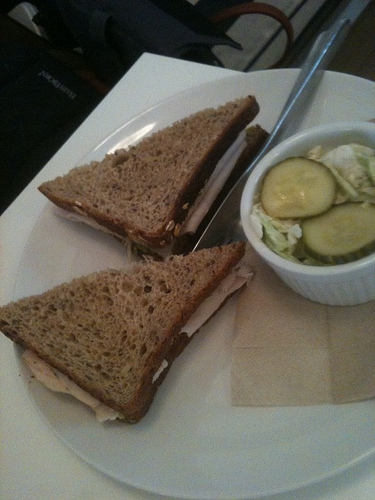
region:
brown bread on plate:
[107, 96, 256, 239]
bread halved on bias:
[30, 82, 242, 409]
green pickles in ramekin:
[284, 155, 363, 269]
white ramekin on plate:
[228, 128, 371, 301]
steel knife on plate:
[178, 44, 336, 262]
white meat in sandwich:
[10, 275, 253, 416]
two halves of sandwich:
[30, 136, 261, 433]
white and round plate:
[17, 134, 363, 483]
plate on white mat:
[44, 112, 364, 482]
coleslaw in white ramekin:
[256, 139, 363, 238]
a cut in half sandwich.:
[36, 91, 267, 257]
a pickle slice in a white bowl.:
[257, 155, 338, 224]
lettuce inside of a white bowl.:
[243, 198, 303, 261]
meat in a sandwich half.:
[174, 125, 252, 243]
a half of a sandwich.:
[0, 239, 255, 424]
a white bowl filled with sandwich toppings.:
[237, 115, 373, 306]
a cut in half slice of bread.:
[0, 237, 248, 405]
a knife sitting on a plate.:
[186, 0, 372, 258]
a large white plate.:
[11, 68, 374, 498]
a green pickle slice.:
[298, 199, 374, 267]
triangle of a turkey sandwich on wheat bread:
[0, 243, 256, 427]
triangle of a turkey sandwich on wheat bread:
[30, 85, 273, 266]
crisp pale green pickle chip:
[259, 145, 344, 221]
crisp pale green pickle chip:
[296, 194, 374, 269]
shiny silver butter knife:
[180, 11, 358, 257]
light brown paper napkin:
[219, 226, 371, 419]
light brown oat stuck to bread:
[162, 217, 176, 232]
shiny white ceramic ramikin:
[237, 113, 373, 312]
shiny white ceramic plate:
[1, 65, 372, 498]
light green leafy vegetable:
[244, 194, 316, 270]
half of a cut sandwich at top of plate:
[35, 94, 270, 261]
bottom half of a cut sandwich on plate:
[1, 239, 255, 425]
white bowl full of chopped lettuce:
[237, 118, 373, 306]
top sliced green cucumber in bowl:
[259, 154, 339, 220]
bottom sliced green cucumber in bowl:
[300, 200, 374, 264]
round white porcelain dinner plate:
[1, 68, 374, 499]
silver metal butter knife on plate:
[170, 1, 373, 254]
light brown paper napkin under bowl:
[230, 238, 374, 406]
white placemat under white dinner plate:
[1, 51, 374, 499]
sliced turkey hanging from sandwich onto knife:
[180, 132, 245, 233]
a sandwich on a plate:
[54, 86, 281, 417]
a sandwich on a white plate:
[48, 88, 322, 427]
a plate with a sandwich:
[13, 214, 306, 487]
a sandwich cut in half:
[41, 232, 281, 495]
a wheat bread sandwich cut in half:
[17, 231, 263, 428]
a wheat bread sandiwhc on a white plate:
[31, 174, 189, 385]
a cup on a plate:
[219, 166, 372, 371]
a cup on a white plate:
[203, 120, 372, 340]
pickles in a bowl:
[234, 155, 361, 279]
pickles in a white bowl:
[221, 97, 373, 279]